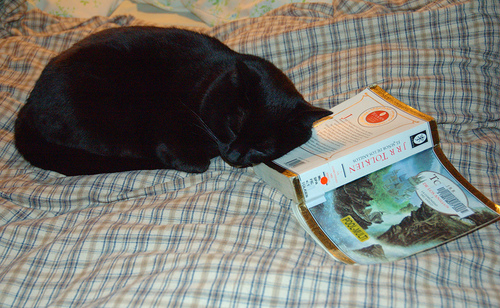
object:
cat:
[14, 23, 332, 178]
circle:
[365, 106, 389, 123]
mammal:
[11, 17, 342, 205]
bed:
[14, 173, 257, 298]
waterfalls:
[349, 171, 444, 223]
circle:
[317, 170, 330, 184]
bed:
[12, 7, 472, 294]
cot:
[9, 3, 497, 306]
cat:
[18, 15, 347, 170]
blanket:
[9, 86, 362, 306]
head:
[197, 63, 348, 178]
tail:
[7, 102, 164, 177]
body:
[13, 25, 228, 171]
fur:
[41, 32, 220, 141]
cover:
[295, 144, 499, 267]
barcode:
[285, 152, 306, 177]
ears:
[230, 58, 340, 120]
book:
[302, 66, 436, 228]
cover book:
[262, 84, 425, 174]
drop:
[322, 178, 331, 189]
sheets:
[3, 4, 498, 304]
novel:
[254, 83, 498, 273]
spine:
[293, 123, 435, 194]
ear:
[221, 52, 267, 94]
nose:
[222, 141, 248, 166]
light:
[57, 0, 281, 18]